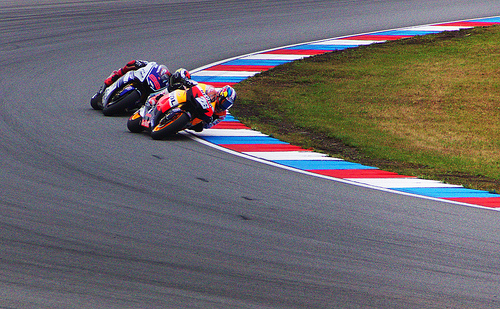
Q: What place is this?
A: It is a road.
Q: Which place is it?
A: It is a road.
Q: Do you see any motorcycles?
A: Yes, there is a motorcycle.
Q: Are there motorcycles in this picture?
A: Yes, there is a motorcycle.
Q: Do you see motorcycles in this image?
A: Yes, there is a motorcycle.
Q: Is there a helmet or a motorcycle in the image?
A: Yes, there is a motorcycle.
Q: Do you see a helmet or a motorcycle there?
A: Yes, there is a motorcycle.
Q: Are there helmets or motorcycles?
A: Yes, there is a motorcycle.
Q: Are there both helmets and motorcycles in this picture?
A: Yes, there are both a motorcycle and a helmet.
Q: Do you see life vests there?
A: No, there are no life vests.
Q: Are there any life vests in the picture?
A: No, there are no life vests.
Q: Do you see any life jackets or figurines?
A: No, there are no life jackets or figurines.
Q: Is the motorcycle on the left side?
A: Yes, the motorcycle is on the left of the image.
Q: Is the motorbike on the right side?
A: No, the motorbike is on the left of the image.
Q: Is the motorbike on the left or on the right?
A: The motorbike is on the left of the image.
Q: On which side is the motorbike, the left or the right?
A: The motorbike is on the left of the image.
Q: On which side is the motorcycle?
A: The motorcycle is on the left of the image.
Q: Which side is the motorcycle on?
A: The motorcycle is on the left of the image.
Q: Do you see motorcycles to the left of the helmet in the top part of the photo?
A: Yes, there is a motorcycle to the left of the helmet.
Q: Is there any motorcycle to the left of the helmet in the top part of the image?
A: Yes, there is a motorcycle to the left of the helmet.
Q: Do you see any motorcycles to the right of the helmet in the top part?
A: No, the motorcycle is to the left of the helmet.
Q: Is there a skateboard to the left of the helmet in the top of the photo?
A: No, there is a motorcycle to the left of the helmet.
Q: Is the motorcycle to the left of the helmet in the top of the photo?
A: Yes, the motorcycle is to the left of the helmet.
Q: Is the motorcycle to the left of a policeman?
A: No, the motorcycle is to the left of the helmet.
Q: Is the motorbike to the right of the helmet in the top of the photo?
A: No, the motorbike is to the left of the helmet.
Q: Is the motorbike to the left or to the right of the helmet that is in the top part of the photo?
A: The motorbike is to the left of the helmet.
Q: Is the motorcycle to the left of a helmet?
A: Yes, the motorcycle is to the left of a helmet.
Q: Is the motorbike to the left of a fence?
A: No, the motorbike is to the left of a helmet.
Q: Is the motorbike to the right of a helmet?
A: No, the motorbike is to the left of a helmet.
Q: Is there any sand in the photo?
A: Yes, there is sand.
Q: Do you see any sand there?
A: Yes, there is sand.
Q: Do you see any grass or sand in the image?
A: Yes, there is sand.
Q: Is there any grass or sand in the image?
A: Yes, there is sand.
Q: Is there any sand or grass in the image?
A: Yes, there is sand.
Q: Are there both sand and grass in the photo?
A: Yes, there are both sand and grass.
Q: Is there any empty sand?
A: Yes, there is empty sand.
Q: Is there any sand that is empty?
A: Yes, there is sand that is empty.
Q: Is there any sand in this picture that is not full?
A: Yes, there is empty sand.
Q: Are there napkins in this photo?
A: No, there are no napkins.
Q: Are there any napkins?
A: No, there are no napkins.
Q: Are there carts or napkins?
A: No, there are no napkins or carts.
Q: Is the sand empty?
A: Yes, the sand is empty.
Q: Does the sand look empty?
A: Yes, the sand is empty.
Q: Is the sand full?
A: No, the sand is empty.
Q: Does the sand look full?
A: No, the sand is empty.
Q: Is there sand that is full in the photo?
A: No, there is sand but it is empty.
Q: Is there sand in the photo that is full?
A: No, there is sand but it is empty.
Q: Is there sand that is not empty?
A: No, there is sand but it is empty.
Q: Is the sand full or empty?
A: The sand is empty.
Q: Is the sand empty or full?
A: The sand is empty.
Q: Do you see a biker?
A: Yes, there is a biker.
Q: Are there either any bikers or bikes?
A: Yes, there is a biker.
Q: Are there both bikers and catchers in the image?
A: No, there is a biker but no catchers.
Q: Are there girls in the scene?
A: No, there are no girls.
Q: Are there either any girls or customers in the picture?
A: No, there are no girls or customers.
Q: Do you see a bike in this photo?
A: Yes, there is a bike.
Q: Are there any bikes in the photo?
A: Yes, there is a bike.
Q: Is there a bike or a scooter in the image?
A: Yes, there is a bike.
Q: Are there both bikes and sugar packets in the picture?
A: No, there is a bike but no sugar packets.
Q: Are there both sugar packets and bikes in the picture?
A: No, there is a bike but no sugar packets.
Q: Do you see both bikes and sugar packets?
A: No, there is a bike but no sugar packets.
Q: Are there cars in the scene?
A: No, there are no cars.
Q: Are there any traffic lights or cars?
A: No, there are no cars or traffic lights.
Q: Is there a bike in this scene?
A: Yes, there is a bike.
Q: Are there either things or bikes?
A: Yes, there is a bike.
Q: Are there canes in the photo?
A: No, there are no canes.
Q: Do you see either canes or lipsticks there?
A: No, there are no canes or lipsticks.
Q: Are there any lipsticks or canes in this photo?
A: No, there are no canes or lipsticks.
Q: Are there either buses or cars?
A: No, there are no cars or buses.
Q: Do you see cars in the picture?
A: No, there are no cars.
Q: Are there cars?
A: No, there are no cars.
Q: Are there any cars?
A: No, there are no cars.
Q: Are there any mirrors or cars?
A: No, there are no cars or mirrors.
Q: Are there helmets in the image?
A: Yes, there is a helmet.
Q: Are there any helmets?
A: Yes, there is a helmet.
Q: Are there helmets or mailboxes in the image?
A: Yes, there is a helmet.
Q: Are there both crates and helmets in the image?
A: No, there is a helmet but no crates.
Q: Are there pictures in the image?
A: No, there are no pictures.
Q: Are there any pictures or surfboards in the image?
A: No, there are no pictures or surfboards.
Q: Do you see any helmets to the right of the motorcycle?
A: Yes, there is a helmet to the right of the motorcycle.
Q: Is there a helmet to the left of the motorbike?
A: No, the helmet is to the right of the motorbike.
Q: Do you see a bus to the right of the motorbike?
A: No, there is a helmet to the right of the motorbike.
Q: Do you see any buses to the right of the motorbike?
A: No, there is a helmet to the right of the motorbike.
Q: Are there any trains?
A: Yes, there is a train.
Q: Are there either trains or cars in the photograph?
A: Yes, there is a train.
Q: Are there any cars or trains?
A: Yes, there is a train.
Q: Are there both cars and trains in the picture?
A: No, there is a train but no cars.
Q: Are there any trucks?
A: No, there are no trucks.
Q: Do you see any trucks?
A: No, there are no trucks.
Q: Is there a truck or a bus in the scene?
A: No, there are no trucks or buses.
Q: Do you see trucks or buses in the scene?
A: No, there are no trucks or buses.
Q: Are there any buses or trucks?
A: No, there are no trucks or buses.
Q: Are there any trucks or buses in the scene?
A: No, there are no trucks or buses.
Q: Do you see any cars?
A: No, there are no cars.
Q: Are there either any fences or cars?
A: No, there are no cars or fences.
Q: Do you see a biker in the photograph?
A: Yes, there is a biker.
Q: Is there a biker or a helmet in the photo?
A: Yes, there is a biker.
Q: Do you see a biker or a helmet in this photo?
A: Yes, there is a biker.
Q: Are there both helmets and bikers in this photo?
A: Yes, there are both a biker and a helmet.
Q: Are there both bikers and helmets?
A: Yes, there are both a biker and a helmet.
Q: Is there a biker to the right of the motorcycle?
A: Yes, there is a biker to the right of the motorcycle.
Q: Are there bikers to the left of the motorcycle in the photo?
A: No, the biker is to the right of the motorcycle.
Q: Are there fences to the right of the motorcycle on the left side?
A: No, there is a biker to the right of the motorbike.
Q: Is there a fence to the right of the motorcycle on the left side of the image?
A: No, there is a biker to the right of the motorbike.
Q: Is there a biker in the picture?
A: Yes, there is a biker.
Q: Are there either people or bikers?
A: Yes, there is a biker.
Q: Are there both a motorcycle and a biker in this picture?
A: Yes, there are both a biker and a motorcycle.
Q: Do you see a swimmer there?
A: No, there are no swimmers.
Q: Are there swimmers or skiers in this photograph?
A: No, there are no swimmers or skiers.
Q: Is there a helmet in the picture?
A: Yes, there is a helmet.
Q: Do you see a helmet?
A: Yes, there is a helmet.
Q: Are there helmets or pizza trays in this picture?
A: Yes, there is a helmet.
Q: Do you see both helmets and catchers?
A: No, there is a helmet but no catchers.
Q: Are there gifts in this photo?
A: No, there are no gifts.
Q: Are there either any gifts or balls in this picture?
A: No, there are no gifts or balls.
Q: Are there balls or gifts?
A: No, there are no gifts or balls.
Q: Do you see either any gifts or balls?
A: No, there are no gifts or balls.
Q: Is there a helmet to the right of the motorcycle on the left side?
A: Yes, there is a helmet to the right of the motorcycle.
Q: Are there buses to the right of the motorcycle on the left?
A: No, there is a helmet to the right of the motorcycle.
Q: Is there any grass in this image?
A: Yes, there is grass.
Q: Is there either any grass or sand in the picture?
A: Yes, there is grass.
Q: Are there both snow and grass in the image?
A: No, there is grass but no snow.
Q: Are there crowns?
A: No, there are no crowns.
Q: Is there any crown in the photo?
A: No, there are no crowns.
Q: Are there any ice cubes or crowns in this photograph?
A: No, there are no crowns or ice cubes.